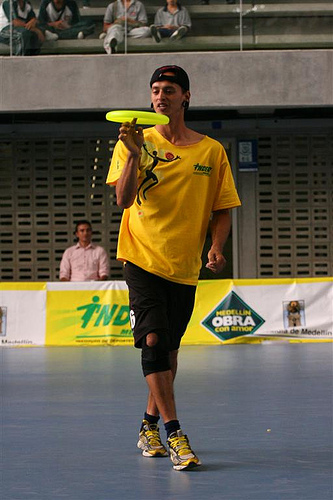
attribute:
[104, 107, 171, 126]
frisbee — yellow, bright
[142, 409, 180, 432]
socks — black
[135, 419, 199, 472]
sneakers — yellow, gray, grey, white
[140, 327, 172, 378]
brace — black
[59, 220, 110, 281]
man — watching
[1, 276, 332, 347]
banner — large, yellow, white, checkered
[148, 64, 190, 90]
hat — black, backwards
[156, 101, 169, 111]
mouth — open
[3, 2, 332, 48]
bleachers — cement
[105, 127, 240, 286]
shirt — yellow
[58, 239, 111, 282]
shirt — pink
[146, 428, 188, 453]
laces — yellow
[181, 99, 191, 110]
earring — black, gauged, large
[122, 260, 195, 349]
shorts — black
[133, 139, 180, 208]
design — black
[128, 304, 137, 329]
number — white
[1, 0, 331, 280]
building — concrete